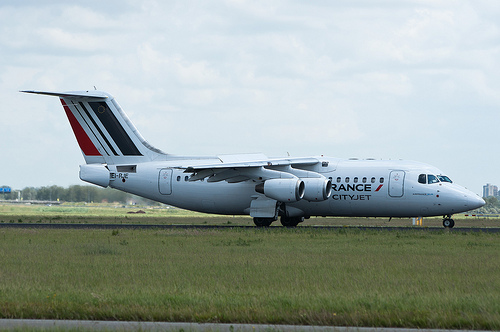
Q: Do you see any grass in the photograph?
A: Yes, there is grass.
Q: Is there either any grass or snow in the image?
A: Yes, there is grass.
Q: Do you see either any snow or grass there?
A: Yes, there is grass.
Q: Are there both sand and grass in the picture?
A: No, there is grass but no sand.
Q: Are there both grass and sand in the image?
A: No, there is grass but no sand.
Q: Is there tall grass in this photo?
A: Yes, there is tall grass.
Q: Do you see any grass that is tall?
A: Yes, there is grass that is tall.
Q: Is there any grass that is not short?
A: Yes, there is tall grass.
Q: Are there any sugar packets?
A: No, there are no sugar packets.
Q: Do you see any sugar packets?
A: No, there are no sugar packets.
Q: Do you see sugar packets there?
A: No, there are no sugar packets.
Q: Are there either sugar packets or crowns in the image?
A: No, there are no sugar packets or crowns.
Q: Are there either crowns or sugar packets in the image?
A: No, there are no sugar packets or crowns.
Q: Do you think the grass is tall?
A: Yes, the grass is tall.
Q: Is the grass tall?
A: Yes, the grass is tall.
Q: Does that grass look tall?
A: Yes, the grass is tall.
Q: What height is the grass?
A: The grass is tall.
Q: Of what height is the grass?
A: The grass is tall.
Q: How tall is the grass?
A: The grass is tall.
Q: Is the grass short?
A: No, the grass is tall.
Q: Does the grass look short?
A: No, the grass is tall.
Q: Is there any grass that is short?
A: No, there is grass but it is tall.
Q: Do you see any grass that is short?
A: No, there is grass but it is tall.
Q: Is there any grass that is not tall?
A: No, there is grass but it is tall.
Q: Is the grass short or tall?
A: The grass is tall.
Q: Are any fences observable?
A: No, there are no fences.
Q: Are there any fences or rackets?
A: No, there are no fences or rackets.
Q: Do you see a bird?
A: No, there are no birds.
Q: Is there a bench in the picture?
A: No, there are no benches.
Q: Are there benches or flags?
A: No, there are no benches or flags.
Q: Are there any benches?
A: No, there are no benches.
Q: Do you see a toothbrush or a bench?
A: No, there are no benches or toothbrushes.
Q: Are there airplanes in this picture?
A: Yes, there is an airplane.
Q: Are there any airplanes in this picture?
A: Yes, there is an airplane.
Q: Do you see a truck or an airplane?
A: Yes, there is an airplane.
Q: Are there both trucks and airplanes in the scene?
A: No, there is an airplane but no trucks.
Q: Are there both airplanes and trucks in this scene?
A: No, there is an airplane but no trucks.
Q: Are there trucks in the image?
A: No, there are no trucks.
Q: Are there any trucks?
A: No, there are no trucks.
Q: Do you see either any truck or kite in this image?
A: No, there are no trucks or kites.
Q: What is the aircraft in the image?
A: The aircraft is an airplane.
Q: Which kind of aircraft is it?
A: The aircraft is an airplane.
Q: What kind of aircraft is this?
A: That is an airplane.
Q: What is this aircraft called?
A: That is an airplane.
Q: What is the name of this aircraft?
A: That is an airplane.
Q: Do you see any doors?
A: Yes, there is a door.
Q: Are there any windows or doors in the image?
A: Yes, there is a door.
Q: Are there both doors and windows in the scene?
A: Yes, there are both a door and a window.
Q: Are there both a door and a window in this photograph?
A: Yes, there are both a door and a window.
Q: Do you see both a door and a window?
A: Yes, there are both a door and a window.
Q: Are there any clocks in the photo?
A: No, there are no clocks.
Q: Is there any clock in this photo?
A: No, there are no clocks.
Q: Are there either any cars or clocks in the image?
A: No, there are no clocks or cars.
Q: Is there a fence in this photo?
A: No, there are no fences.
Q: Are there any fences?
A: No, there are no fences.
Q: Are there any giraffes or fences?
A: No, there are no fences or giraffes.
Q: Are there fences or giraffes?
A: No, there are no fences or giraffes.